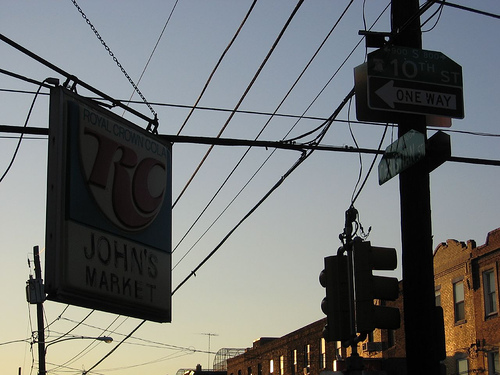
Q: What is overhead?
A: Power Lines.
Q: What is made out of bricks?
A: Tall buildings.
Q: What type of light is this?
A: Traffic light.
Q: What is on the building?
A: Windows.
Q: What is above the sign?
A: A metal pole.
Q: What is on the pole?
A: A light.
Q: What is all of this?
A: Poles ,wires and buildings.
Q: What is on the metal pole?
A: A chain.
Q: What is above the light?
A: Cables and wires.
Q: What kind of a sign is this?
A: A "One Way" sign.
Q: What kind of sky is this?
A: Light blue.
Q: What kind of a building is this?
A: Dark red.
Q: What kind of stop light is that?
A: A red stop light.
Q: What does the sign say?
A: John's Market.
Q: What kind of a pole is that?
A: A utility pole.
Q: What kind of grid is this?
A: A power grid.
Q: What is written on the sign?
A: RC John's Market.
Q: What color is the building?
A: Brown.